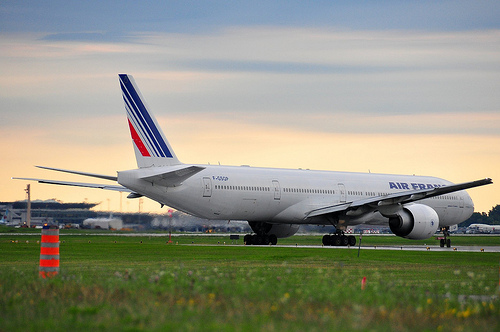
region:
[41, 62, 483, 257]
plane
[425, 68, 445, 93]
white clouds in blue sky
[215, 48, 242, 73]
white clouds in blue sky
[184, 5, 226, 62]
white clouds in blue sky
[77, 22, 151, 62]
white clouds in blue sky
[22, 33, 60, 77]
white clouds in blue sky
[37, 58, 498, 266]
this is a white airplane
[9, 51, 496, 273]
this is a white passenger jet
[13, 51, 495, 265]
this is a white passenger jet engine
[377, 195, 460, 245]
this is an engine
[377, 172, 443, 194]
the letters are blue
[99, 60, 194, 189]
the tail has red, white, and blue stripes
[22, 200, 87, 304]
this is an orange cone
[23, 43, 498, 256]
the plane is on a runway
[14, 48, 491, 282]
the plane is in an airfield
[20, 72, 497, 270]
plane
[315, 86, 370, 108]
white clouds in blue sky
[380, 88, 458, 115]
white clouds in blue sky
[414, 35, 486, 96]
white clouds in blue sky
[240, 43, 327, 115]
white clouds in blue sky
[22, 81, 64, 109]
white clouds in blue sky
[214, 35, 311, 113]
white clouds in blue sky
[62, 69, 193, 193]
tail of a plane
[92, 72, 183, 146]
wing of a plane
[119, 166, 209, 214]
wing of a plane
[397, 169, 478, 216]
wing of a plane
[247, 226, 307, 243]
wheel of a plane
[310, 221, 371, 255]
wheel of a plane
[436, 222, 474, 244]
wheel of a plane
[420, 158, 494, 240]
front of a plane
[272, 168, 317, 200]
window of a plane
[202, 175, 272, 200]
window of a plane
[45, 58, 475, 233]
plane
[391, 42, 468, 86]
white clouds in blue sky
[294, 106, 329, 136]
white clouds in blue sky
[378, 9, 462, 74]
white clouds in blue sky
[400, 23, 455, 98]
white clouds in blue sky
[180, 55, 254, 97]
white clouds in blue sky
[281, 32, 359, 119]
white clouds in blue sky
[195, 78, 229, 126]
white clouds in blue sky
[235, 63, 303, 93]
white clouds in blue sky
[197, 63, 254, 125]
white clouds in blue sky